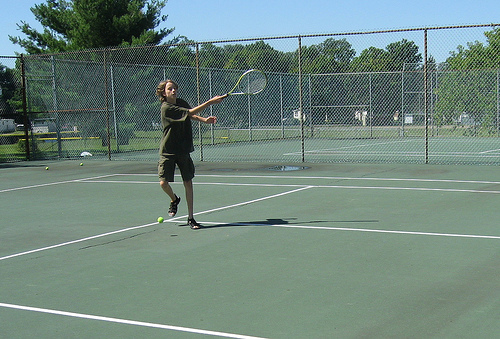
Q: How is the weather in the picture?
A: It is clear.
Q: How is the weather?
A: It is clear.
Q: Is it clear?
A: Yes, it is clear.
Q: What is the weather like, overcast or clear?
A: It is clear.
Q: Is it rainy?
A: No, it is clear.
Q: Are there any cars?
A: No, there are no cars.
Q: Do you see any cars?
A: No, there are no cars.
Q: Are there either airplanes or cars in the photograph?
A: No, there are no cars or airplanes.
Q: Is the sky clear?
A: Yes, the sky is clear.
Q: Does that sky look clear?
A: Yes, the sky is clear.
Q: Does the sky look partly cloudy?
A: No, the sky is clear.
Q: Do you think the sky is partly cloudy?
A: No, the sky is clear.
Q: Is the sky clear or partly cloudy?
A: The sky is clear.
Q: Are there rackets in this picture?
A: Yes, there is a racket.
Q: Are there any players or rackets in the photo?
A: Yes, there is a racket.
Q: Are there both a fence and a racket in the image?
A: Yes, there are both a racket and a fence.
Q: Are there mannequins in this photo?
A: No, there are no mannequins.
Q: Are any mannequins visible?
A: No, there are no mannequins.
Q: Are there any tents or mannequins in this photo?
A: No, there are no mannequins or tents.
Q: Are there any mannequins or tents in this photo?
A: No, there are no mannequins or tents.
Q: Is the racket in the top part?
A: Yes, the racket is in the top of the image.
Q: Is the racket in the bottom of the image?
A: No, the racket is in the top of the image.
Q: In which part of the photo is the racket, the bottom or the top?
A: The racket is in the top of the image.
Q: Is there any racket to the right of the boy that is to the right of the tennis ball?
A: Yes, there is a racket to the right of the boy.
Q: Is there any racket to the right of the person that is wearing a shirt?
A: Yes, there is a racket to the right of the boy.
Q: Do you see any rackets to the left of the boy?
A: No, the racket is to the right of the boy.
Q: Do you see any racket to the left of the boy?
A: No, the racket is to the right of the boy.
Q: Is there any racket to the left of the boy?
A: No, the racket is to the right of the boy.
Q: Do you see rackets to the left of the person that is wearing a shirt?
A: No, the racket is to the right of the boy.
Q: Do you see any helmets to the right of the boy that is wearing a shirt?
A: No, there is a racket to the right of the boy.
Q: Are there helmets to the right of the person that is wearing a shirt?
A: No, there is a racket to the right of the boy.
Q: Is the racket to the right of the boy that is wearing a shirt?
A: Yes, the racket is to the right of the boy.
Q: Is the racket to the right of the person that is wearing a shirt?
A: Yes, the racket is to the right of the boy.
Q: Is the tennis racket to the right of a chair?
A: No, the tennis racket is to the right of the boy.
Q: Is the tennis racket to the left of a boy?
A: No, the tennis racket is to the right of a boy.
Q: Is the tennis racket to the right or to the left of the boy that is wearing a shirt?
A: The tennis racket is to the right of the boy.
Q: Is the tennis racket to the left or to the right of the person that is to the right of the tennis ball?
A: The tennis racket is to the right of the boy.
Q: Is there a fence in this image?
A: Yes, there is a fence.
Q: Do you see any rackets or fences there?
A: Yes, there is a fence.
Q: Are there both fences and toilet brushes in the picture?
A: No, there is a fence but no toilet brushes.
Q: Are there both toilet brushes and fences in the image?
A: No, there is a fence but no toilet brushes.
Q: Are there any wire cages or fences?
A: Yes, there is a wire fence.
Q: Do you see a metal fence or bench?
A: Yes, there is a metal fence.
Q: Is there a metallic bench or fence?
A: Yes, there is a metal fence.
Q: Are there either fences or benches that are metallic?
A: Yes, the fence is metallic.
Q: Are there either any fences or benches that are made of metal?
A: Yes, the fence is made of metal.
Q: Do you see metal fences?
A: Yes, there is a metal fence.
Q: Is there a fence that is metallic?
A: Yes, there is a fence that is metallic.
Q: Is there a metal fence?
A: Yes, there is a fence that is made of metal.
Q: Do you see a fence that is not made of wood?
A: Yes, there is a fence that is made of metal.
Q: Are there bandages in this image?
A: No, there are no bandages.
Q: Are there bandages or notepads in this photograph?
A: No, there are no bandages or notepads.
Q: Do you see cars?
A: No, there are no cars.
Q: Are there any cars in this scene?
A: No, there are no cars.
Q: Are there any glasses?
A: No, there are no glasses.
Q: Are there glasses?
A: No, there are no glasses.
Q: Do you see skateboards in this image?
A: No, there are no skateboards.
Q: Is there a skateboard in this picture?
A: No, there are no skateboards.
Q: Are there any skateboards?
A: No, there are no skateboards.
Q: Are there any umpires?
A: No, there are no umpires.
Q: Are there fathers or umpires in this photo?
A: No, there are no umpires or fathers.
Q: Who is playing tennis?
A: The boy is playing tennis.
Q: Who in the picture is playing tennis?
A: The boy is playing tennis.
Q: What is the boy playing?
A: The boy is playing tennis.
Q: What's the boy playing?
A: The boy is playing tennis.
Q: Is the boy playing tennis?
A: Yes, the boy is playing tennis.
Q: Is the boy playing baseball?
A: No, the boy is playing tennis.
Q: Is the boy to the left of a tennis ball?
A: No, the boy is to the right of a tennis ball.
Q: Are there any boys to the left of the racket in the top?
A: Yes, there is a boy to the left of the racket.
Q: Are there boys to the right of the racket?
A: No, the boy is to the left of the racket.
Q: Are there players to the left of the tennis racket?
A: No, there is a boy to the left of the tennis racket.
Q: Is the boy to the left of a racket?
A: Yes, the boy is to the left of a racket.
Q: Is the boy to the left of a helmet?
A: No, the boy is to the left of a racket.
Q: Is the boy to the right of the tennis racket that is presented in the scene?
A: No, the boy is to the left of the tennis racket.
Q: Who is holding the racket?
A: The boy is holding the racket.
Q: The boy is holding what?
A: The boy is holding the tennis racket.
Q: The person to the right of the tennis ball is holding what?
A: The boy is holding the tennis racket.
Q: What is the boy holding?
A: The boy is holding the tennis racket.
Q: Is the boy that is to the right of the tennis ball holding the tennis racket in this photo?
A: Yes, the boy is holding the tennis racket.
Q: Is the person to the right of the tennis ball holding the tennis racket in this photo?
A: Yes, the boy is holding the tennis racket.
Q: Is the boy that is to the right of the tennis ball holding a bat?
A: No, the boy is holding the tennis racket.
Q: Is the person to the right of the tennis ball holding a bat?
A: No, the boy is holding the tennis racket.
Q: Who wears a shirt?
A: The boy wears a shirt.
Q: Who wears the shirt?
A: The boy wears a shirt.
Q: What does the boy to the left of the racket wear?
A: The boy wears a shirt.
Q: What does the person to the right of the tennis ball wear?
A: The boy wears a shirt.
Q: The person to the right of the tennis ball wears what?
A: The boy wears a shirt.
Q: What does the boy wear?
A: The boy wears a shirt.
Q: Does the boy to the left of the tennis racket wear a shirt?
A: Yes, the boy wears a shirt.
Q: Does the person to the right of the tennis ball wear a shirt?
A: Yes, the boy wears a shirt.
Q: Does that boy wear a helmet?
A: No, the boy wears a shirt.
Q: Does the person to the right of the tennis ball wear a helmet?
A: No, the boy wears a shirt.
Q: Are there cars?
A: No, there are no cars.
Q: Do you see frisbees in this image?
A: No, there are no frisbees.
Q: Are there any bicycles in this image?
A: No, there are no bicycles.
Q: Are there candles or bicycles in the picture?
A: No, there are no bicycles or candles.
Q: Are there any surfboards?
A: No, there are no surfboards.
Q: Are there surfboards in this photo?
A: No, there are no surfboards.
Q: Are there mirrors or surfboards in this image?
A: No, there are no surfboards or mirrors.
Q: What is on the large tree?
A: The leaves are on the tree.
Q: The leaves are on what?
A: The leaves are on the tree.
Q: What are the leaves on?
A: The leaves are on the tree.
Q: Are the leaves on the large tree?
A: Yes, the leaves are on the tree.